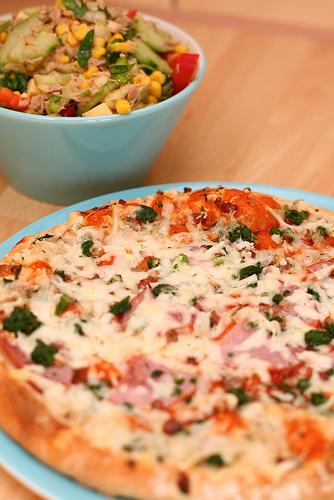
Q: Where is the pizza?
A: On the table.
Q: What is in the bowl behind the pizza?
A: Salad.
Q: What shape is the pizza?
A: Round.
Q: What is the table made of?
A: Wood.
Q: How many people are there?
A: None.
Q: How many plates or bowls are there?
A: Two.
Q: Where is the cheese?
A: On the pizza.